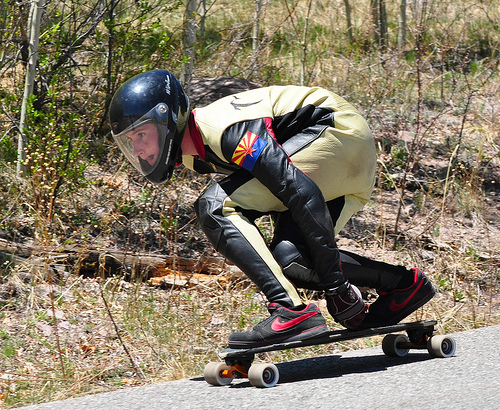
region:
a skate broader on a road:
[100, 63, 457, 409]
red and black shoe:
[217, 299, 344, 351]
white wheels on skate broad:
[201, 358, 283, 393]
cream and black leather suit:
[199, 78, 416, 305]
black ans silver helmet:
[99, 65, 201, 185]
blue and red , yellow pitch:
[222, 125, 274, 177]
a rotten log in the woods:
[9, 253, 217, 300]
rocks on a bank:
[400, 95, 485, 194]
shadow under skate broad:
[199, 344, 441, 393]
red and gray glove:
[324, 269, 390, 341]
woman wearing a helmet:
[56, 48, 247, 197]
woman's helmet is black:
[80, 60, 217, 190]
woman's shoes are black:
[194, 225, 427, 341]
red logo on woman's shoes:
[256, 278, 426, 331]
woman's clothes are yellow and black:
[192, 72, 383, 252]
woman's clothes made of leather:
[207, 82, 404, 277]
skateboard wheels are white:
[184, 337, 293, 395]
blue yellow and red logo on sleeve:
[224, 121, 274, 168]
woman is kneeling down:
[68, 42, 413, 339]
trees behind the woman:
[3, 6, 492, 251]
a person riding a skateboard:
[101, 68, 435, 347]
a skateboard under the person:
[202, 318, 457, 387]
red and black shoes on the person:
[227, 265, 434, 347]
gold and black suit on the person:
[181, 80, 412, 306]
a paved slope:
[0, 318, 498, 408]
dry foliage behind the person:
[0, 0, 499, 409]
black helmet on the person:
[104, 68, 188, 188]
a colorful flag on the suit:
[232, 128, 268, 170]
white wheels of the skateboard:
[204, 333, 456, 387]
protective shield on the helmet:
[109, 103, 169, 178]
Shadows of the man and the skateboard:
[190, 354, 447, 390]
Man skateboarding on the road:
[107, 69, 436, 349]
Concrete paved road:
[11, 327, 498, 407]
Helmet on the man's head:
[106, 70, 188, 185]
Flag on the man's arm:
[231, 130, 266, 172]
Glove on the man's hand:
[323, 285, 373, 330]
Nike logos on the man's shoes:
[271, 278, 426, 331]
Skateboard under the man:
[203, 320, 455, 388]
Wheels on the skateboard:
[203, 334, 457, 389]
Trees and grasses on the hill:
[0, 1, 496, 405]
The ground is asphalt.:
[3, 320, 499, 408]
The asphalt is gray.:
[1, 320, 497, 405]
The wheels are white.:
[203, 331, 459, 388]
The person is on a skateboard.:
[106, 68, 458, 387]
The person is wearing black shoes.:
[218, 265, 437, 349]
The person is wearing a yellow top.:
[181, 83, 374, 195]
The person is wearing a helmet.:
[106, 67, 193, 186]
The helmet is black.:
[105, 67, 188, 187]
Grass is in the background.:
[0, 0, 499, 408]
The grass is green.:
[0, 0, 499, 404]